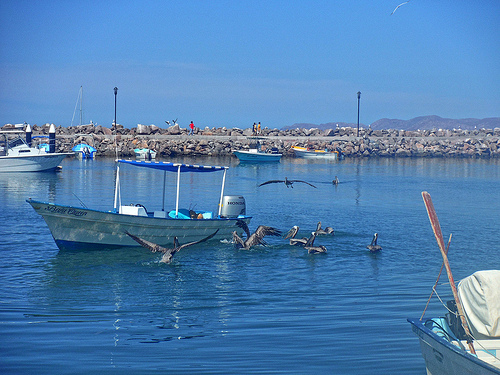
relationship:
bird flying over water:
[252, 172, 321, 200] [2, 156, 498, 372]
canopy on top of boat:
[110, 155, 227, 224] [25, 156, 256, 255]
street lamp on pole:
[111, 84, 120, 94] [112, 97, 119, 127]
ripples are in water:
[132, 274, 319, 354] [108, 239, 388, 359]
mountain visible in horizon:
[263, 105, 498, 138] [0, 116, 497, 124]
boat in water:
[232, 146, 284, 165] [2, 156, 498, 372]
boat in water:
[26, 157, 256, 251] [2, 156, 498, 372]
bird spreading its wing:
[120, 224, 220, 265] [183, 228, 223, 254]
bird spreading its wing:
[120, 224, 220, 265] [118, 223, 164, 253]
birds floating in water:
[119, 218, 386, 267] [2, 156, 498, 372]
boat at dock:
[3, 120, 85, 183] [0, 127, 80, 180]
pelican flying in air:
[263, 170, 311, 196] [1, 0, 499, 373]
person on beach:
[256, 121, 263, 136] [0, 125, 499, 158]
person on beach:
[188, 120, 195, 135] [0, 125, 499, 158]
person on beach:
[251, 122, 257, 135] [0, 125, 499, 158]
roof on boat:
[116, 158, 228, 172] [26, 196, 252, 253]